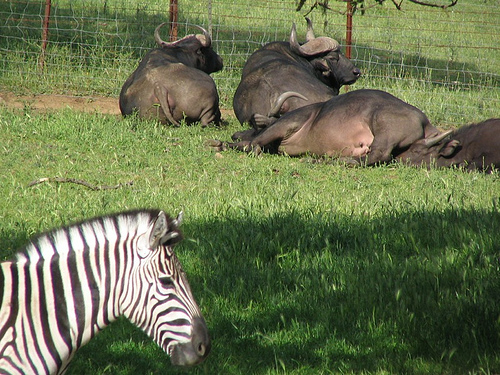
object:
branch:
[26, 176, 133, 191]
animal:
[203, 89, 442, 168]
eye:
[328, 57, 338, 63]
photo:
[81, 112, 358, 342]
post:
[37, 0, 52, 74]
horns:
[152, 21, 212, 46]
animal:
[0, 208, 211, 374]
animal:
[233, 17, 361, 127]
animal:
[395, 117, 500, 173]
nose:
[192, 314, 212, 357]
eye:
[158, 276, 175, 287]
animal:
[119, 23, 223, 128]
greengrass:
[2, 0, 499, 372]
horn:
[289, 17, 340, 56]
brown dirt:
[0, 92, 122, 116]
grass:
[0, 0, 500, 372]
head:
[119, 208, 212, 367]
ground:
[4, 5, 497, 365]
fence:
[0, 0, 500, 124]